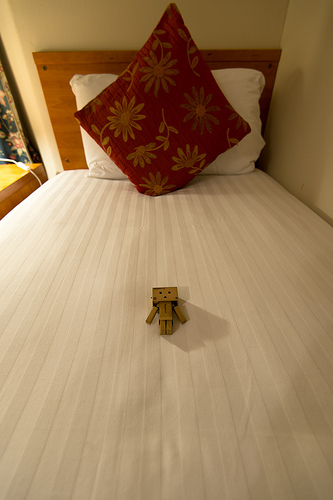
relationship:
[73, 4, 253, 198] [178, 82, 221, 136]
pillow has a flower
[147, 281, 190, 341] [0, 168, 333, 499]
doll on bed spread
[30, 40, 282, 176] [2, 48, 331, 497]
wood part at top of bed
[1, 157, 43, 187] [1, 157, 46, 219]
cord hanging from table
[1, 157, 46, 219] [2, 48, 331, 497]
table next to bed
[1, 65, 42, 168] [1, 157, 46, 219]
floral print on table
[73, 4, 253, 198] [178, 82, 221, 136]
pillow has a floral pattern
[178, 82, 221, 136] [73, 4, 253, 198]
flower on pillow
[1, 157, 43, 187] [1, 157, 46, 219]
cord hanging on table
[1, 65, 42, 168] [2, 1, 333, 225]
curtain hanging on wall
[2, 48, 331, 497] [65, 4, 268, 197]
bed has two pillows